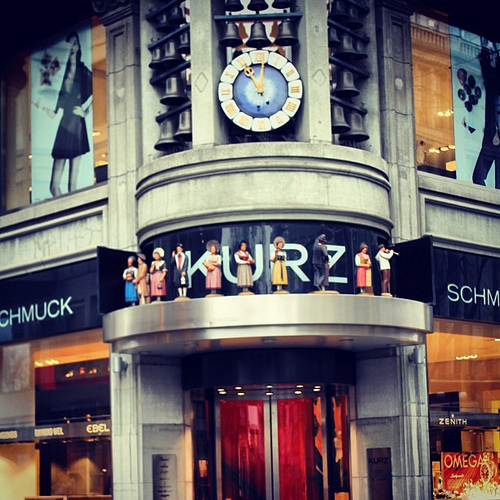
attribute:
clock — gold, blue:
[208, 50, 325, 144]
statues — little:
[104, 232, 406, 302]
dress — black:
[44, 58, 108, 174]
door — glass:
[170, 369, 360, 494]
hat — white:
[148, 234, 170, 264]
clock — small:
[204, 47, 307, 144]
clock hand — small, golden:
[240, 47, 273, 97]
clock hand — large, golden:
[228, 22, 278, 94]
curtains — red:
[214, 369, 320, 490]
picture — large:
[23, 32, 102, 202]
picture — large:
[6, 256, 459, 500]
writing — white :
[24, 264, 104, 352]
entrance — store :
[94, 297, 434, 485]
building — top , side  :
[4, 11, 462, 463]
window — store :
[434, 316, 484, 479]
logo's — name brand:
[2, 297, 75, 332]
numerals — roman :
[281, 99, 300, 113]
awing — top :
[107, 223, 417, 308]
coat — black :
[311, 244, 333, 288]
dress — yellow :
[268, 246, 288, 283]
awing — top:
[111, 237, 411, 294]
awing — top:
[113, 227, 406, 304]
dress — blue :
[118, 269, 138, 304]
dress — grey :
[234, 254, 259, 290]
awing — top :
[114, 220, 412, 300]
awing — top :
[106, 233, 406, 293]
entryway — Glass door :
[185, 370, 357, 492]